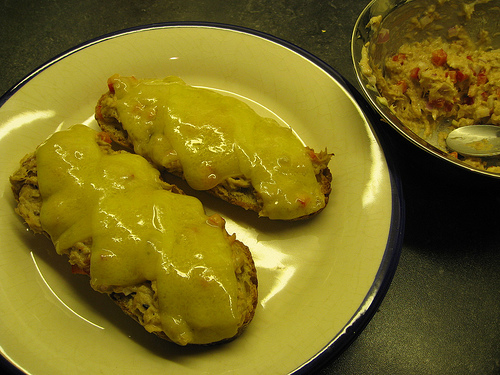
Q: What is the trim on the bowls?
A: Silver.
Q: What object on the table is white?
A: Plate.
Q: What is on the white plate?
A: Food.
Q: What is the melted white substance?
A: Cheese.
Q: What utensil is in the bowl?
A: Spoon.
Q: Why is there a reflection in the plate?
A: It is shiny.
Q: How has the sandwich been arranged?
A: In two pieces.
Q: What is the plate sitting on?
A: Table.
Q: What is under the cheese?
A: Bread.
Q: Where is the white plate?
A: On the table.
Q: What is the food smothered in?
A: Creamy sauce.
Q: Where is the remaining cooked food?
A: In the pot.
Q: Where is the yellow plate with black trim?
A: On the table.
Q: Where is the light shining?
A: Along the sauce's surface.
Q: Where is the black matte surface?
A: On the table.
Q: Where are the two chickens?
A: On a plate.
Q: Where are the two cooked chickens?
A: On a plate.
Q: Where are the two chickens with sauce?
A: On a white plate.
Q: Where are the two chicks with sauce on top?
A: On a white plate.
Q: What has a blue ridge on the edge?
A: A plate.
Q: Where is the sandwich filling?
A: In a bowl.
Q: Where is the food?
A: On the plate.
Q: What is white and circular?
A: The plate.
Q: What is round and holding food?
A: The plate.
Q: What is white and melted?
A: The cheese.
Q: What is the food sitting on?
A: A plate.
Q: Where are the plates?
A: On a table.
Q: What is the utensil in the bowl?
A: A spoon.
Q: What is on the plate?
A: Food.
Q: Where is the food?
A: On the plate.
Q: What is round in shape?
A: The plate.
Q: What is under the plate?
A: The table.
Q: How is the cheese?
A: Melted.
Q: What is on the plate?
A: Food.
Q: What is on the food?
A: Cheese.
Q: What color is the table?
A: Black.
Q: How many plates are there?
A: One.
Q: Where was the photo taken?
A: In a dining room.